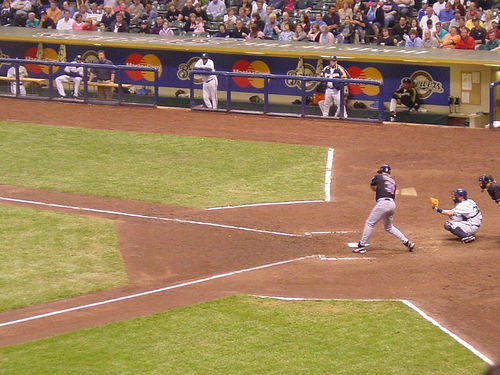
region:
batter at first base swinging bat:
[354, 161, 425, 258]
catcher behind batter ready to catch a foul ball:
[427, 186, 487, 247]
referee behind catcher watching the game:
[476, 170, 498, 206]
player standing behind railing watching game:
[318, 53, 346, 114]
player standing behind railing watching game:
[192, 53, 222, 106]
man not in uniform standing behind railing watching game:
[83, 51, 117, 100]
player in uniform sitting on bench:
[379, 75, 420, 122]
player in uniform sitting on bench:
[48, 52, 83, 94]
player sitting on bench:
[6, 59, 33, 92]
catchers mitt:
[427, 194, 439, 212]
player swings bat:
[356, 166, 413, 253]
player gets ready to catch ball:
[425, 188, 481, 245]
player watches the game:
[53, 56, 84, 94]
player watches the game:
[191, 55, 220, 109]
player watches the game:
[316, 56, 347, 116]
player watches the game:
[383, 76, 418, 119]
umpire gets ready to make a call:
[473, 171, 499, 208]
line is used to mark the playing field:
[0, 195, 316, 242]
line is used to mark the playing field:
[0, 248, 320, 328]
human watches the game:
[53, 10, 73, 32]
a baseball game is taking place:
[11, 10, 497, 350]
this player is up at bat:
[343, 152, 418, 264]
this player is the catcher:
[422, 178, 484, 245]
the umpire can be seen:
[478, 159, 498, 221]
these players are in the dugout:
[4, 47, 432, 119]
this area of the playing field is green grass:
[26, 128, 260, 202]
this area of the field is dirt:
[230, 189, 492, 318]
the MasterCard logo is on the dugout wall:
[118, 53, 164, 85]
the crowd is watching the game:
[6, 3, 488, 55]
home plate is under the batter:
[343, 235, 371, 257]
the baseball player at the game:
[430, 187, 479, 242]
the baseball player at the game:
[357, 166, 412, 251]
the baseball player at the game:
[315, 55, 351, 120]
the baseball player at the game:
[387, 77, 416, 121]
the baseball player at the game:
[4, 58, 27, 94]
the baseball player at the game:
[54, 53, 88, 98]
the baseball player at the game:
[190, 53, 217, 110]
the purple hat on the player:
[450, 188, 467, 199]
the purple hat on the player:
[329, 56, 336, 62]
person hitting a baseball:
[309, 150, 454, 277]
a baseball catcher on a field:
[423, 173, 484, 248]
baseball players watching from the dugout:
[1, 41, 498, 134]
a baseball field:
[9, 82, 485, 356]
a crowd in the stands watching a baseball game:
[5, 0, 487, 70]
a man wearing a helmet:
[449, 184, 471, 206]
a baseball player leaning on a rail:
[183, 46, 240, 139]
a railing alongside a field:
[179, 52, 447, 140]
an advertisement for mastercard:
[113, 48, 168, 88]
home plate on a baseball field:
[333, 221, 379, 278]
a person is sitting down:
[439, 25, 459, 45]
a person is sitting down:
[458, 25, 474, 50]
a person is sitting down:
[400, 30, 426, 50]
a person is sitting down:
[415, 30, 437, 47]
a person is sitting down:
[315, 20, 338, 42]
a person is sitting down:
[288, 25, 309, 42]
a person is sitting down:
[273, 19, 296, 42]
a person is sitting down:
[244, 22, 263, 38]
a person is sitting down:
[213, 24, 234, 37]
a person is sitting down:
[232, 18, 249, 36]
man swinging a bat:
[348, 145, 424, 265]